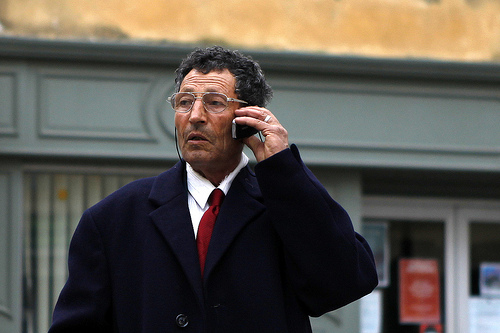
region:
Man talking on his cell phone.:
[46, 43, 378, 331]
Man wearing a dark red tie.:
[46, 43, 378, 331]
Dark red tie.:
[191, 186, 226, 276]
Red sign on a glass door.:
[396, 255, 441, 323]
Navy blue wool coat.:
[43, 143, 378, 332]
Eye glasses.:
[166, 90, 253, 115]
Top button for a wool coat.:
[173, 310, 191, 329]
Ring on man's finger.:
[264, 113, 271, 123]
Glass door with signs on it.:
[362, 204, 457, 331]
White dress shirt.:
[183, 150, 249, 237]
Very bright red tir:
[189, 179, 233, 276]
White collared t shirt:
[182, 165, 244, 252]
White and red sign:
[398, 248, 448, 328]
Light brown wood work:
[305, 6, 425, 33]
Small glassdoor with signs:
[365, 208, 460, 331]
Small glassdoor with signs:
[461, 210, 496, 319]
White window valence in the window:
[35, 173, 49, 331]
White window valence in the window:
[50, 176, 64, 288]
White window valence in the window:
[70, 174, 88, 246]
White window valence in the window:
[86, 177, 101, 204]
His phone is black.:
[229, 107, 260, 142]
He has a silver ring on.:
[256, 112, 275, 123]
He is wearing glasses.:
[161, 82, 248, 117]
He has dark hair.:
[172, 40, 274, 120]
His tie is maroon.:
[189, 185, 220, 270]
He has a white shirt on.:
[178, 160, 238, 263]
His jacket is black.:
[60, 157, 380, 327]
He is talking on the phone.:
[145, 57, 282, 194]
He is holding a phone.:
[156, 46, 291, 192]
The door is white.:
[353, 193, 490, 331]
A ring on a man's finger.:
[260, 112, 271, 123]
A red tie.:
[196, 184, 224, 275]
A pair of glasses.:
[165, 89, 249, 116]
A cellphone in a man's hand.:
[230, 114, 264, 141]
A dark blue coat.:
[49, 159, 381, 331]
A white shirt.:
[186, 151, 251, 237]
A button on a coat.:
[174, 310, 190, 325]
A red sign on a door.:
[396, 256, 443, 326]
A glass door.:
[359, 216, 443, 331]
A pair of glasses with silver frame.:
[165, 90, 249, 114]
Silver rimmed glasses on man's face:
[172, 88, 247, 107]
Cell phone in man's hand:
[227, 115, 261, 135]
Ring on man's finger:
[265, 113, 270, 123]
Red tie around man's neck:
[195, 190, 222, 270]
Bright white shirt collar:
[183, 155, 250, 195]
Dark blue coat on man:
[47, 145, 377, 329]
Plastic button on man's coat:
[174, 310, 188, 326]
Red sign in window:
[398, 258, 440, 322]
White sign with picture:
[476, 262, 498, 294]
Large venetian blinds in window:
[27, 175, 137, 316]